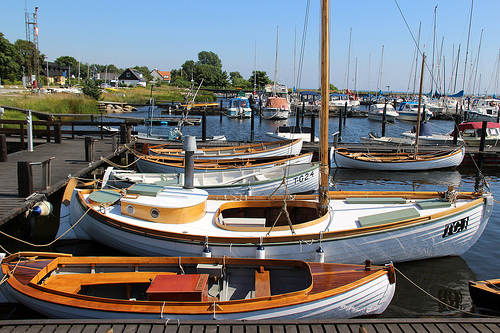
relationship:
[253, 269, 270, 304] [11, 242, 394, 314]
bench on boat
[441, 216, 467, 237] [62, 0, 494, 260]
sign on a boat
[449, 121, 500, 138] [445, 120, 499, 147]
maroon cover over boat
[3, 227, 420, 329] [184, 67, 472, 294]
boat in harbor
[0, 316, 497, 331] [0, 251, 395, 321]
pier beside boat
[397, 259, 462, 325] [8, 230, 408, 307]
rope tying boat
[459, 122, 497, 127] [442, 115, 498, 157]
boat with maroon cover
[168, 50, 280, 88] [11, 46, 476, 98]
trees in distance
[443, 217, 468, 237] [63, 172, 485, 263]
tgi painted on boat